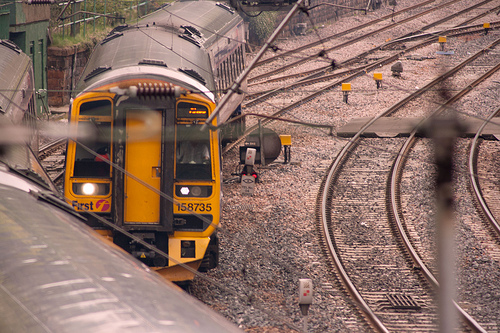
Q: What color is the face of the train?
A: Yellow.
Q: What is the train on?
A: Train tracks.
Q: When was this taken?
A: Daytime.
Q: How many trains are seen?
A: 2.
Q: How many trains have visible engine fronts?
A: 1.